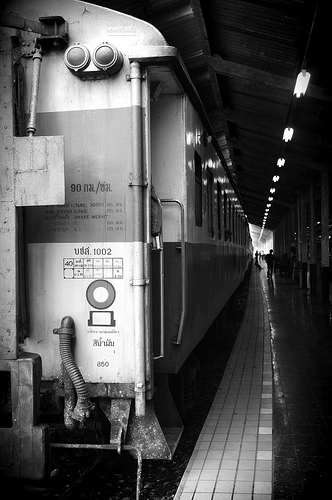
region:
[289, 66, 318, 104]
this is a bulb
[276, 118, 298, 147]
this is a bulb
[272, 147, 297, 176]
this is a bulb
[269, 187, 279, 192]
this is a bulb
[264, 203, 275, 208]
this is a bulb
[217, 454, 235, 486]
these are blocks on the floor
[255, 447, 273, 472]
these are blocks on the floor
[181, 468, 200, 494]
these are blocks on the floor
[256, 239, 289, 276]
people on the platform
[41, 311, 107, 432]
Hose on the back of the train.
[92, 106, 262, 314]
Train at the train station.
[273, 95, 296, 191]
Lights on the ceiling.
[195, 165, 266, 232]
Windows on the train.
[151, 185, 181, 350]
Handle on the train.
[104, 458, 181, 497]
Gravel and rocks on the tracks.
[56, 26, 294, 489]
The photo is black and white.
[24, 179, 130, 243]
Writing and numbers on the train.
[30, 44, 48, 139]
Pipe on the train.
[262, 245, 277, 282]
Person standing near train.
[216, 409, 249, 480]
White tiles on train platform.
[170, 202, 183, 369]
Railings near door way on train car.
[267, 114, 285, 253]
Lights on ceiling near train.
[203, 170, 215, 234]
Window on side of train car.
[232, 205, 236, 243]
Window on side of train car.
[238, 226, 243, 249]
Window on side of train car.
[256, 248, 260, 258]
People in distance walking near train.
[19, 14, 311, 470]
old black and white photo of a train and platform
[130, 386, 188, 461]
step up to the train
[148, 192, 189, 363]
hand rails for stepping up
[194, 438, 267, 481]
square tiles on the platform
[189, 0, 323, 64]
ceiling of the station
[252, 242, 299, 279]
people waiting on the platform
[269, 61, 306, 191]
hanging fluorescent lights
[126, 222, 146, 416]
end of a drain pipe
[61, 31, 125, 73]
2 circular black and white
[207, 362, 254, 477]
a black and white tiles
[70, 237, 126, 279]
numbers and letters can be read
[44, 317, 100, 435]
a long black pipe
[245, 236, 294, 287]
people in the distance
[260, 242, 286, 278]
person appears all black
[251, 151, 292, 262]
a row of white lights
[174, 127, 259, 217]
reflection from the lights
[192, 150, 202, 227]
A window on a vehicle.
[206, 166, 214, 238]
A window on a vehicle.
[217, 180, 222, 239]
A window on a vehicle.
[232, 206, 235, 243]
A window on a vehicle.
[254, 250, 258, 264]
A person is standing up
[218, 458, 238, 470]
A tile in a floor.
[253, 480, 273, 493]
A tile in a floor.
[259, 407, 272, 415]
A tile in a floor.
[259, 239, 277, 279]
person standing on the platform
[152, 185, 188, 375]
handle bar on the train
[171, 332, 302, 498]
tiles on the platform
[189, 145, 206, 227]
window on the train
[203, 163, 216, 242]
window on the train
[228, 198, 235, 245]
window on the train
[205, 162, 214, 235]
window on the train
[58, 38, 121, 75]
red light on the train